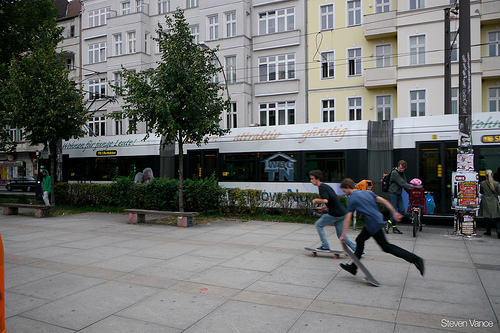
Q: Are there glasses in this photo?
A: No, there are no glasses.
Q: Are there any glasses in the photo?
A: No, there are no glasses.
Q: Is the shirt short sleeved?
A: Yes, the shirt is short sleeved.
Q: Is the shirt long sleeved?
A: No, the shirt is short sleeved.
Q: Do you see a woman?
A: Yes, there is a woman.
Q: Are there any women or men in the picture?
A: Yes, there is a woman.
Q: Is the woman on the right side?
A: Yes, the woman is on the right of the image.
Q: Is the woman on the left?
A: No, the woman is on the right of the image.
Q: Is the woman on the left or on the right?
A: The woman is on the right of the image.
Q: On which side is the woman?
A: The woman is on the right of the image.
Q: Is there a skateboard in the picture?
A: Yes, there is a skateboard.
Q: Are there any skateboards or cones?
A: Yes, there is a skateboard.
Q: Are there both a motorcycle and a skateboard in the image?
A: No, there is a skateboard but no motorcycles.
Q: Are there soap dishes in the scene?
A: No, there are no soap dishes.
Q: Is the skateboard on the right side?
A: Yes, the skateboard is on the right of the image.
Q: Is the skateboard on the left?
A: No, the skateboard is on the right of the image.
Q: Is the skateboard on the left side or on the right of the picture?
A: The skateboard is on the right of the image.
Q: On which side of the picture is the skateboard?
A: The skateboard is on the right of the image.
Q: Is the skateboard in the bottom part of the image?
A: Yes, the skateboard is in the bottom of the image.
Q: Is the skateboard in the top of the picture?
A: No, the skateboard is in the bottom of the image.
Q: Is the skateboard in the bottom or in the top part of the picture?
A: The skateboard is in the bottom of the image.